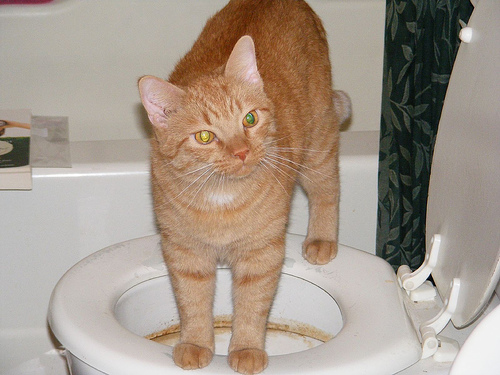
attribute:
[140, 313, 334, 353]
ring — dirt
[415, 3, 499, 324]
lid — up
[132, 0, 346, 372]
cat — orange, brown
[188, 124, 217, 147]
eye — yellow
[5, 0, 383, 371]
bathtub — white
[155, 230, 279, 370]
legs — cat